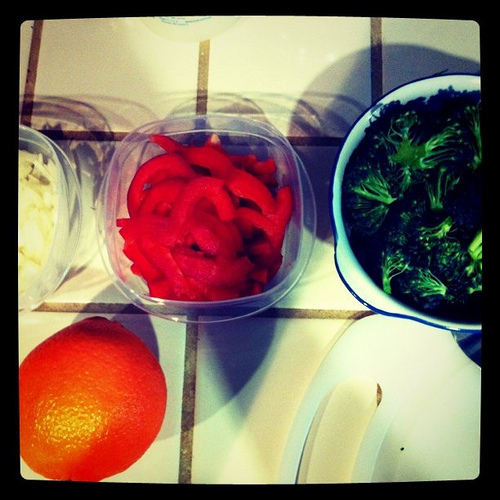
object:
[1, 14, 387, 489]
lines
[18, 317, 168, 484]
fruit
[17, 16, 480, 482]
counter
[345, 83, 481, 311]
broccoli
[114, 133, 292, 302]
pieces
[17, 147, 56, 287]
pieces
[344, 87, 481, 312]
pieces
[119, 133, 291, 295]
peppers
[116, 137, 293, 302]
food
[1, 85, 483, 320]
vegetables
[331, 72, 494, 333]
bowl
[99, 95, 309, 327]
bowl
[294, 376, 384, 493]
banana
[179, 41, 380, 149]
tile